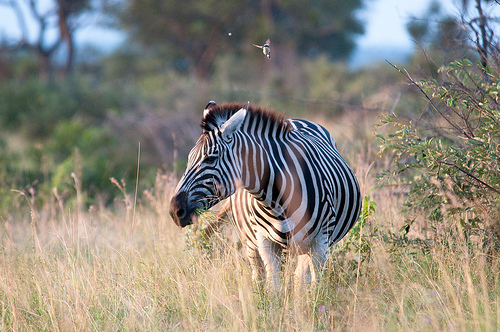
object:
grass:
[0, 155, 499, 331]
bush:
[370, 0, 499, 260]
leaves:
[389, 137, 435, 151]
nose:
[168, 195, 187, 221]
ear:
[221, 100, 250, 133]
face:
[169, 134, 229, 228]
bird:
[252, 38, 271, 60]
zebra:
[167, 100, 362, 318]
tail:
[204, 210, 226, 242]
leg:
[247, 247, 328, 294]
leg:
[308, 235, 335, 322]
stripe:
[238, 130, 248, 185]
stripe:
[185, 169, 220, 191]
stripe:
[229, 132, 244, 179]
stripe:
[210, 127, 219, 153]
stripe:
[323, 219, 337, 231]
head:
[169, 99, 250, 228]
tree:
[0, 0, 499, 250]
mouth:
[169, 208, 198, 228]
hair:
[199, 101, 293, 131]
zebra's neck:
[234, 129, 267, 202]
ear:
[204, 100, 215, 118]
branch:
[374, 0, 500, 263]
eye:
[203, 156, 219, 163]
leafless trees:
[0, 0, 55, 79]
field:
[0, 105, 499, 332]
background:
[0, 0, 498, 329]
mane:
[198, 100, 292, 130]